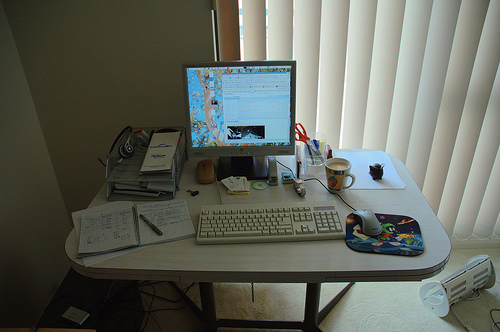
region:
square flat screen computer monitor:
[179, 57, 301, 184]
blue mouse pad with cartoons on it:
[343, 206, 425, 256]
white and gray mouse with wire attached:
[271, 154, 386, 239]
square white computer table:
[61, 107, 456, 329]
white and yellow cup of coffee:
[318, 156, 357, 197]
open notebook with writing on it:
[78, 194, 198, 254]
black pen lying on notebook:
[135, 208, 166, 238]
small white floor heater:
[418, 244, 498, 323]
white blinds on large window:
[232, 0, 498, 248]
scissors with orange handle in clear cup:
[291, 117, 331, 168]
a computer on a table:
[147, 41, 355, 261]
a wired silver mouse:
[345, 191, 385, 251]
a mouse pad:
[350, 202, 421, 262]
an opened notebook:
[70, 197, 192, 247]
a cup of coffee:
[322, 152, 358, 192]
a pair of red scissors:
[293, 117, 314, 147]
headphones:
[114, 119, 149, 159]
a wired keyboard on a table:
[194, 186, 348, 252]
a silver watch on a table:
[292, 174, 313, 200]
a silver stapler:
[266, 152, 284, 189]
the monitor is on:
[168, 52, 357, 168]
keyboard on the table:
[193, 196, 364, 246]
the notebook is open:
[71, 190, 206, 261]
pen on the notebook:
[130, 205, 185, 250]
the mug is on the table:
[320, 148, 363, 214]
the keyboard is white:
[167, 180, 409, 267]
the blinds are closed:
[208, 17, 498, 212]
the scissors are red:
[294, 119, 330, 170]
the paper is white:
[325, 134, 439, 224]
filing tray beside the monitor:
[88, 106, 183, 219]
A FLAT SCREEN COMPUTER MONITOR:
[180, 55, 308, 170]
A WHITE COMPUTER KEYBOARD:
[189, 200, 359, 250]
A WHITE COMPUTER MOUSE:
[349, 196, 394, 241]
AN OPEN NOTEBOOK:
[67, 187, 205, 262]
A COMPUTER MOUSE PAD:
[339, 207, 441, 259]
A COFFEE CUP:
[315, 151, 360, 195]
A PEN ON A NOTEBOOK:
[131, 203, 199, 250]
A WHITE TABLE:
[63, 140, 462, 293]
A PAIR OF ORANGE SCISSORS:
[289, 120, 312, 147]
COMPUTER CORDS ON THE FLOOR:
[79, 267, 203, 328]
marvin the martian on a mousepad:
[343, 206, 425, 259]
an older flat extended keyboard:
[192, 196, 346, 248]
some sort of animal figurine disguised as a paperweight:
[365, 158, 388, 183]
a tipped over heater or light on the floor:
[410, 246, 495, 321]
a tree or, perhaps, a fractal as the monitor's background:
[185, 68, 227, 150]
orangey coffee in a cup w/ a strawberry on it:
[320, 154, 355, 194]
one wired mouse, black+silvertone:
[273, 154, 392, 241]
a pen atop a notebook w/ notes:
[66, 191, 198, 261]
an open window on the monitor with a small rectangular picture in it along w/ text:
[222, 74, 288, 144]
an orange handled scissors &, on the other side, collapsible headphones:
[115, 118, 324, 160]